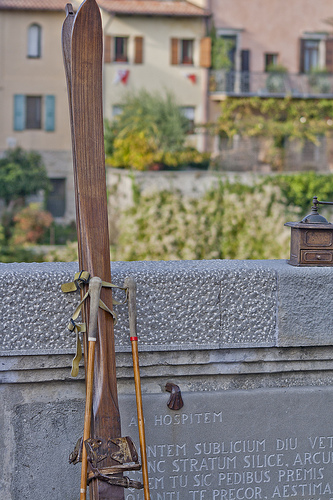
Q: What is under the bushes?
A: Block with inscription.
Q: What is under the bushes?
A: Inscription on wall.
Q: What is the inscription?
A: Brown skis.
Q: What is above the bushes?
A: Two buildings.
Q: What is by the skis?
A: Shrubbery.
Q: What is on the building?
A: Vines on wall.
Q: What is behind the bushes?
A: Gray wall.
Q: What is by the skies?
A: Plaque on monument.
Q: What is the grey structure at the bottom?
A: A gray concrete monument.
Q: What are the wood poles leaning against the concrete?
A: Two old skis and ski poles.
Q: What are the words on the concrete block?
A: An inscription.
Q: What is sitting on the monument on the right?
A: A metal box.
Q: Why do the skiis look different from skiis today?
A: They are an antique.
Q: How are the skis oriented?
A: They are leaning up against the monument.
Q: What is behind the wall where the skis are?
A: There is an old building behind the wall where the skis are.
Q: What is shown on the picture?
A: Its the top part of wall where old skis lay.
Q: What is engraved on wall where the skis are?
A: The words are engraved on wall where skis are.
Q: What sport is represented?
A: Skiing.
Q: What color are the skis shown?
A: Brown.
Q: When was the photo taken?
A: Daytime.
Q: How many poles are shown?
A: Two.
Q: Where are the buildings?
A: Background.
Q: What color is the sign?
A: Gray.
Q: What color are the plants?
A: Green.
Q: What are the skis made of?
A: Wood.